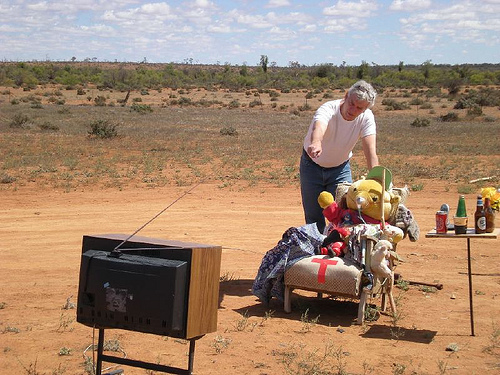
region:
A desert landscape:
[0, 63, 497, 373]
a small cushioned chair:
[281, 183, 408, 322]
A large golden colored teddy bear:
[313, 164, 400, 256]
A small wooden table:
[425, 223, 499, 335]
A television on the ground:
[73, 178, 225, 373]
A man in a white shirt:
[298, 79, 383, 234]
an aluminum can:
[433, 210, 450, 236]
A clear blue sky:
[1, 3, 498, 62]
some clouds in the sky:
[0, 2, 499, 57]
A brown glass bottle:
[473, 196, 488, 232]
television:
[82, 225, 224, 371]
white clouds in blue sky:
[6, 3, 44, 50]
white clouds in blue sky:
[42, 8, 76, 44]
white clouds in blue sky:
[89, 14, 128, 37]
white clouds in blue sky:
[144, 17, 188, 55]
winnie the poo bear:
[335, 166, 398, 227]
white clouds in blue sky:
[136, 14, 174, 50]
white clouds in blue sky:
[200, 8, 252, 57]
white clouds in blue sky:
[274, 3, 345, 63]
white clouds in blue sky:
[325, 8, 385, 50]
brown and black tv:
[40, 216, 225, 356]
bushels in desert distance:
[61, 66, 453, 82]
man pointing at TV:
[287, 106, 403, 198]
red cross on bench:
[308, 236, 350, 307]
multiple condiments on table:
[432, 189, 494, 227]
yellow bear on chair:
[322, 182, 400, 257]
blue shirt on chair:
[250, 222, 332, 293]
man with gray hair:
[344, 85, 394, 119]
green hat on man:
[352, 160, 442, 225]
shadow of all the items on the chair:
[233, 252, 445, 357]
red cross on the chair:
[303, 250, 340, 290]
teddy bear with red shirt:
[312, 172, 398, 252]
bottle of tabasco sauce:
[474, 197, 489, 235]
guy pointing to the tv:
[285, 77, 389, 172]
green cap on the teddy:
[365, 163, 396, 189]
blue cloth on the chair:
[253, 222, 318, 259]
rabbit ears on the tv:
[107, 180, 202, 255]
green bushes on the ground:
[121, 64, 212, 95]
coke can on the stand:
[432, 208, 448, 233]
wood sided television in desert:
[71, 163, 231, 373]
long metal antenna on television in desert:
[111, 171, 249, 256]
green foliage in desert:
[5, 55, 499, 95]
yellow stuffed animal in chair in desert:
[317, 158, 407, 250]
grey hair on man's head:
[343, 78, 380, 108]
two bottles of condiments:
[471, 188, 498, 235]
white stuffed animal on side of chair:
[372, 232, 401, 327]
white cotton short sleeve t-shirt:
[296, 95, 381, 172]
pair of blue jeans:
[294, 149, 359, 239]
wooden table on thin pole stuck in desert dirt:
[423, 219, 496, 338]